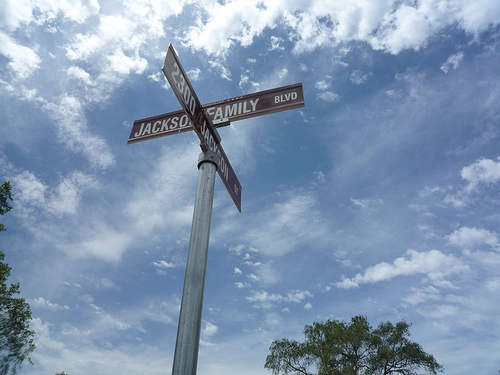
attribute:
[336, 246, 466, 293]
cloud — white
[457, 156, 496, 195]
cloud — white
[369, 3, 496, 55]
cloud — white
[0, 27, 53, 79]
cloud — white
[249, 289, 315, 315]
cloud — white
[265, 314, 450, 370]
leaves — green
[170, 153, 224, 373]
pole — tall, metal, smooth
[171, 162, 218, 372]
pole — metal, gray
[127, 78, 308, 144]
sign — brown, white, English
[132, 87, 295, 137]
writing — sign, white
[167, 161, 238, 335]
post — connected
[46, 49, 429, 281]
sky — blue, above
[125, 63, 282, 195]
sign — rectangular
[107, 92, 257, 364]
pole — metal 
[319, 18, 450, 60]
clouds — white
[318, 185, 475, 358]
cloud — white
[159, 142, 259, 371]
pole — grey 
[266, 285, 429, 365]
tree — green 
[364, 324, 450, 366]
leaves — green 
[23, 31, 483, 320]
sky — blue , cloudy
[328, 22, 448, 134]
clouds — white 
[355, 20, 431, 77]
clouds — white 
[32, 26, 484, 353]
sky — blue 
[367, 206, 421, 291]
clouds — white 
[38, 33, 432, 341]
sky — blue 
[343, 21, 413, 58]
clouds — white 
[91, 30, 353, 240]
signs — white , brown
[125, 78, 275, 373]
pole — gray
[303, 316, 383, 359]
leaves — green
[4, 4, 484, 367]
sky — blue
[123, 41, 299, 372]
sign — brown, silver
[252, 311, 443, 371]
tree — green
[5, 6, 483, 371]
clouds — puffy, white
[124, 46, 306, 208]
signs — brown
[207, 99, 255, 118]
letters — white